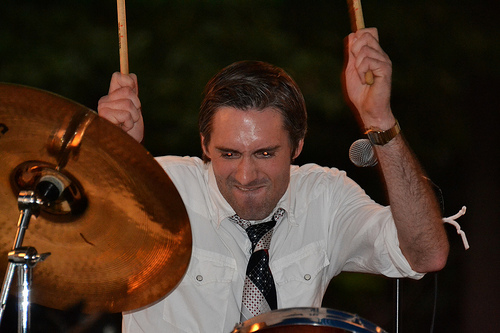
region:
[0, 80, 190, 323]
cymbal of a drum set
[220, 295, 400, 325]
snare drum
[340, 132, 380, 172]
microphone in place for singing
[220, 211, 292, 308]
loosened tie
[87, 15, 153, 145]
drumstick in a drummer's hand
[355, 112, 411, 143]
wrist watch on a man's left hand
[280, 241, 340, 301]
buttoned pocket of a white shirt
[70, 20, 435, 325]
drummer ready to keep up the beat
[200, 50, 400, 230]
determined face of a musician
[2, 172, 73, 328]
metal stands of a drum set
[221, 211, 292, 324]
The tie is black and white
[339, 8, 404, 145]
He is holding a stick.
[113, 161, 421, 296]
He has a white shirt on.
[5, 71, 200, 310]
The cymbal is gold.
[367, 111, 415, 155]
He is wearing a watch.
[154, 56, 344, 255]
He has brown hair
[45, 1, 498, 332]
He is drumming.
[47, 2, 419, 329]
He is pounding the drums.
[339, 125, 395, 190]
The microphone is behind him.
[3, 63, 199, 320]
The cymbal is metal.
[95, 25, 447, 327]
Man playing drums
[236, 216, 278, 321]
Black, white and red tie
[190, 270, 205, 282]
Right pocket button of white shirt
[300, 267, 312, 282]
Left button on white shirt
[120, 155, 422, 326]
White shirt worn by man playing drums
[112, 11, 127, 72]
Drum sticks in right hand of man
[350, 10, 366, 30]
Left hand holding drum stick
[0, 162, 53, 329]
Cymbal drum stand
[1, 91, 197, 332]
Gold ride cymbal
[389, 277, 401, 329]
White line on wall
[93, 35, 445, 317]
Man playing the drums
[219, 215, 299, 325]
Tie on the man's shirt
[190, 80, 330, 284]
The drummer is concentrating very hard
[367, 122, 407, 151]
Watch on drummers wrist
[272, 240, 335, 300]
Pocket on the front of shirt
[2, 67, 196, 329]
Cymbal above the drum set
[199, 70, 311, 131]
Man has brown hair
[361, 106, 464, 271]
Man's arm is hairy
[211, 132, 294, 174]
Man's eyes are squinted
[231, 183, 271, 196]
Man's mouth is pulled in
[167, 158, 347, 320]
the shirt is white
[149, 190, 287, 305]
the shirt is white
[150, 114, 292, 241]
the shirt is white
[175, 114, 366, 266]
the shirt is white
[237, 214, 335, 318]
the shirt is white